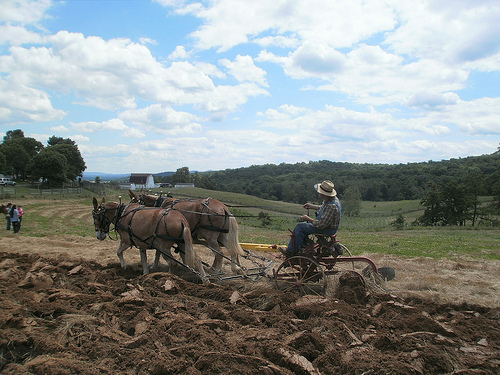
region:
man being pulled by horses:
[268, 171, 381, 294]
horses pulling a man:
[78, 158, 259, 301]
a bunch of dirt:
[49, 286, 221, 374]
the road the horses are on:
[35, 186, 120, 266]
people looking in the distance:
[0, 183, 42, 250]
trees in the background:
[6, 121, 86, 201]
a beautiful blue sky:
[111, 78, 239, 164]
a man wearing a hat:
[299, 170, 341, 208]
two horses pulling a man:
[76, 158, 386, 290]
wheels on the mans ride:
[273, 244, 364, 306]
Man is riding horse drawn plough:
[88, 178, 399, 293]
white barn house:
[129, 172, 196, 191]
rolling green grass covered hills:
[1, 184, 498, 264]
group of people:
[3, 198, 23, 232]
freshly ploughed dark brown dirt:
[1, 243, 498, 373]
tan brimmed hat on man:
[311, 180, 338, 197]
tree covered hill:
[155, 146, 498, 201]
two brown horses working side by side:
[82, 182, 252, 278]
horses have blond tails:
[179, 213, 246, 270]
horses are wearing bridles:
[74, 185, 171, 240]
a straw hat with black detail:
[311, 174, 346, 202]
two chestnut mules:
[81, 179, 265, 289]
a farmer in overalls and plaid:
[278, 166, 365, 261]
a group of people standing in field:
[1, 197, 37, 238]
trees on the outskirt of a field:
[373, 172, 491, 236]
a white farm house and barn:
[116, 165, 206, 196]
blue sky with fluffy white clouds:
[41, 18, 489, 159]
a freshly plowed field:
[18, 279, 480, 365]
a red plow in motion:
[79, 188, 414, 314]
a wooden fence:
[26, 183, 91, 200]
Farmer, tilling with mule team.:
[87, 131, 385, 310]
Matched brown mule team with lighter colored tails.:
[90, 167, 248, 287]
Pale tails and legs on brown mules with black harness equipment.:
[120, 207, 257, 291]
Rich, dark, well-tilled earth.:
[30, 274, 455, 373]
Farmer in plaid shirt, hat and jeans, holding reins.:
[279, 180, 364, 263]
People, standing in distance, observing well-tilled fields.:
[7, 192, 86, 243]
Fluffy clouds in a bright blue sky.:
[14, 68, 402, 129]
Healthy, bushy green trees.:
[0, 130, 85, 189]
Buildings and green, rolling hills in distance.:
[132, 150, 499, 188]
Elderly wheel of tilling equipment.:
[227, 255, 370, 305]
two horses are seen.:
[82, 183, 239, 286]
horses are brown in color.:
[101, 188, 223, 247]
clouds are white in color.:
[80, 41, 235, 126]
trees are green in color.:
[16, 139, 76, 174]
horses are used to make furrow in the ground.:
[96, 166, 441, 327]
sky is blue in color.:
[61, 3, 178, 41]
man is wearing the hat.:
[313, 179, 343, 201]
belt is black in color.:
[88, 196, 180, 258]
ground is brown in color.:
[53, 281, 197, 353]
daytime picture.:
[28, 47, 483, 361]